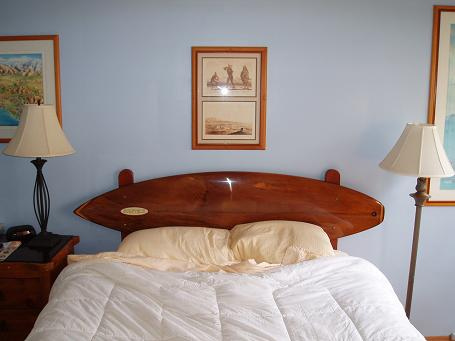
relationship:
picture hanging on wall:
[189, 45, 268, 153] [1, 1, 455, 341]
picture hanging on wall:
[1, 35, 62, 144] [1, 1, 455, 341]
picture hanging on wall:
[419, 4, 453, 206] [1, 1, 455, 341]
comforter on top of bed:
[20, 255, 429, 340] [19, 167, 432, 340]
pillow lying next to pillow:
[113, 225, 230, 269] [229, 218, 334, 264]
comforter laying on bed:
[20, 255, 429, 340] [19, 167, 432, 340]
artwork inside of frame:
[200, 56, 257, 141] [189, 44, 266, 152]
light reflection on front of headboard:
[214, 176, 238, 196] [72, 167, 384, 251]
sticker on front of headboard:
[121, 205, 149, 216] [72, 167, 384, 251]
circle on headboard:
[370, 210, 379, 219] [72, 167, 384, 251]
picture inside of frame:
[201, 56, 258, 98] [189, 44, 266, 152]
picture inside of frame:
[201, 99, 257, 140] [189, 44, 266, 152]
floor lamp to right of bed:
[379, 121, 455, 319] [19, 167, 432, 340]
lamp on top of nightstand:
[5, 100, 76, 251] [1, 234, 80, 341]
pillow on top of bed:
[113, 225, 230, 269] [19, 167, 432, 340]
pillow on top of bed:
[229, 218, 334, 264] [19, 167, 432, 340]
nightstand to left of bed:
[1, 234, 80, 341] [19, 167, 432, 340]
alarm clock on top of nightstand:
[4, 222, 35, 245] [1, 234, 80, 341]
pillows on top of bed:
[117, 218, 336, 264] [19, 167, 432, 340]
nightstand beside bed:
[1, 234, 80, 341] [19, 167, 432, 340]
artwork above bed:
[200, 56, 257, 141] [19, 167, 432, 340]